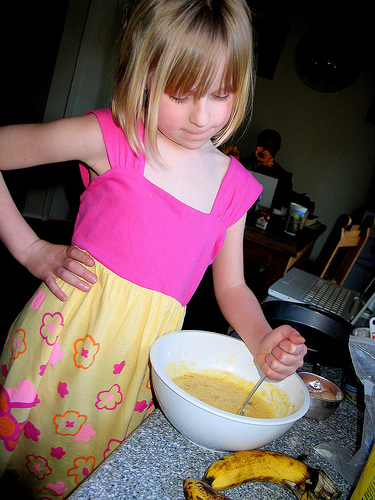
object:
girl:
[1, 1, 307, 500]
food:
[168, 363, 279, 424]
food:
[201, 445, 330, 487]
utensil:
[235, 366, 269, 414]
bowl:
[147, 328, 310, 455]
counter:
[62, 328, 374, 498]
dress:
[2, 106, 262, 498]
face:
[150, 35, 238, 153]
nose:
[189, 103, 210, 129]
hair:
[111, 0, 256, 165]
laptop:
[266, 259, 374, 324]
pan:
[255, 301, 357, 367]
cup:
[282, 202, 309, 237]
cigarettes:
[252, 209, 270, 231]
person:
[244, 127, 288, 193]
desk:
[185, 185, 328, 336]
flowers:
[255, 144, 273, 169]